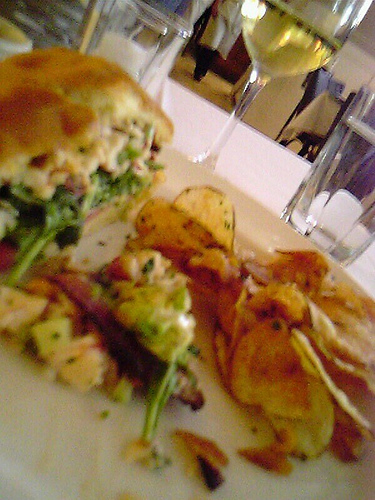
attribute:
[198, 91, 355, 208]
table cloth — white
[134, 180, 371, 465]
chips — handful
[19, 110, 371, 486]
plate — white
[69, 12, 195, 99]
glass — empty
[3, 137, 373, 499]
plate — white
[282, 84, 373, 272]
glass — clear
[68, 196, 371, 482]
plate — white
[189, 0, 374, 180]
glass — large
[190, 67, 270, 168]
handle — long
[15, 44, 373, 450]
food — grouped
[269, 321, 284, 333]
mark — black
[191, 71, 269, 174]
stand — white 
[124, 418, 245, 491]
piece — fallen